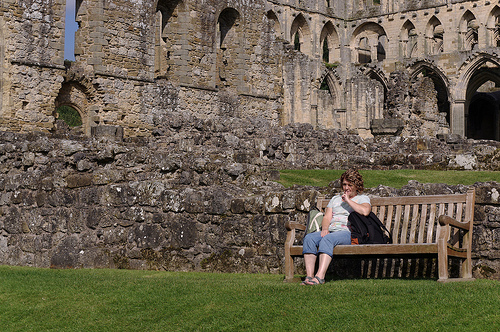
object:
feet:
[305, 277, 326, 285]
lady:
[297, 166, 370, 287]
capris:
[300, 230, 353, 259]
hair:
[337, 167, 365, 193]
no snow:
[0, 121, 498, 331]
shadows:
[325, 254, 461, 281]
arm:
[348, 202, 373, 216]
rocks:
[292, 187, 323, 212]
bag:
[344, 211, 394, 247]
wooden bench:
[278, 183, 473, 280]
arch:
[395, 18, 418, 39]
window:
[395, 19, 418, 59]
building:
[0, 0, 499, 157]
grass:
[0, 264, 498, 331]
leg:
[299, 231, 315, 279]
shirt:
[325, 191, 370, 231]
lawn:
[0, 264, 498, 331]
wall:
[0, 131, 499, 280]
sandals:
[302, 277, 327, 284]